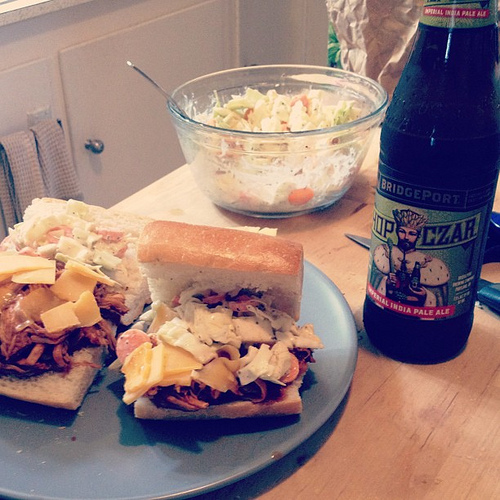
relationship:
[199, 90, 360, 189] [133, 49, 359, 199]
cole slaw in bowl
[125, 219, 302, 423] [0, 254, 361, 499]
sandwich on plate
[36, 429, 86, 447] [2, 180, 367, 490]
crumb on plate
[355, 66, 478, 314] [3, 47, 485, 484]
beer on table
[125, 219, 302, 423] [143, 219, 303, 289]
sandwich on bread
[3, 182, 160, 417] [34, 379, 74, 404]
sandwich on bread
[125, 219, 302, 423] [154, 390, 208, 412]
sandwich with meat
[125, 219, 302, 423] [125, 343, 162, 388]
sandwich with cheese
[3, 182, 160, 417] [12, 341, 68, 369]
sandwich with meat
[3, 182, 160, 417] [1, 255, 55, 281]
sandwich with cheese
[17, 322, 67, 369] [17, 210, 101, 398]
meat in sandwich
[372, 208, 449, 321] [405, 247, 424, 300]
image holding beer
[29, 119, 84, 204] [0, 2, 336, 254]
kitchen towel hanging from cabinet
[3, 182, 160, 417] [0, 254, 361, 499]
sandwich on plate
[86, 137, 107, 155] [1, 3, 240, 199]
door knob on cabinet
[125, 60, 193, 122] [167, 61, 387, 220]
spoon in bowl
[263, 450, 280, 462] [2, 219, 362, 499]
brown spot on plate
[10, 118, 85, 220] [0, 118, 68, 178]
kitchen towel on rack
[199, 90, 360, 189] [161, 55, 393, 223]
cole slaw in bowl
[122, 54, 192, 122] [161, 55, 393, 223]
spoon in bowl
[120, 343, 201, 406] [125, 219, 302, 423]
cheddar cheese on sandwich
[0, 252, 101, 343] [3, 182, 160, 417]
cheese on sandwich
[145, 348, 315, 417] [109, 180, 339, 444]
meat on sandwich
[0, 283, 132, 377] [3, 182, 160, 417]
meat on sandwich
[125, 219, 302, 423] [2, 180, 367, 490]
sandwich on plate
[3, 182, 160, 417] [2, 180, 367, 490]
sandwich on plate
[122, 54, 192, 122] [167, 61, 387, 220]
spoon in bowl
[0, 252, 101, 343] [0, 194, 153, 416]
cheese on sandwich